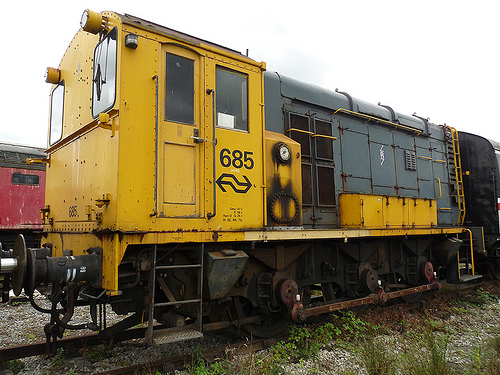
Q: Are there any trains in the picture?
A: Yes, there is a train.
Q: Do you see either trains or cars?
A: Yes, there is a train.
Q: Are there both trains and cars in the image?
A: No, there is a train but no cars.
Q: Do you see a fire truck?
A: No, there are no fire trucks.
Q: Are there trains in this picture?
A: Yes, there is a train.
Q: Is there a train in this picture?
A: Yes, there is a train.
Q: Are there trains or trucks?
A: Yes, there is a train.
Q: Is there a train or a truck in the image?
A: Yes, there is a train.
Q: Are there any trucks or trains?
A: Yes, there is a train.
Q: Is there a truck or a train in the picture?
A: Yes, there is a train.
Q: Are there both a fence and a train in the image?
A: No, there is a train but no fences.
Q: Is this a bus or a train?
A: This is a train.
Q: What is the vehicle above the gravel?
A: The vehicle is a train.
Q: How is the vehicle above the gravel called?
A: The vehicle is a train.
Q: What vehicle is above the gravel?
A: The vehicle is a train.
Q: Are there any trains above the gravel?
A: Yes, there is a train above the gravel.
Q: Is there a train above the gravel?
A: Yes, there is a train above the gravel.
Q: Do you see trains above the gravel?
A: Yes, there is a train above the gravel.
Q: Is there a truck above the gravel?
A: No, there is a train above the gravel.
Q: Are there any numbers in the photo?
A: Yes, there are numbers.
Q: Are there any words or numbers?
A: Yes, there are numbers.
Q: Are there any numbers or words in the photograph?
A: Yes, there are numbers.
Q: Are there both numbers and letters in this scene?
A: No, there are numbers but no letters.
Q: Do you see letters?
A: No, there are no letters.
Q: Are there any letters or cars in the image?
A: No, there are no letters or cars.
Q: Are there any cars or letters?
A: No, there are no letters or cars.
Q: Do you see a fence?
A: No, there are no fences.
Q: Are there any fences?
A: No, there are no fences.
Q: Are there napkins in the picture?
A: No, there are no napkins.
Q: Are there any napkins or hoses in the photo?
A: No, there are no napkins or hoses.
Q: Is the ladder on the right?
A: Yes, the ladder is on the right of the image.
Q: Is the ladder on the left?
A: No, the ladder is on the right of the image.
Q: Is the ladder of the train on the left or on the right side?
A: The ladder is on the right of the image.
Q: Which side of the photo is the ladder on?
A: The ladder is on the right of the image.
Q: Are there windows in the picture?
A: Yes, there is a window.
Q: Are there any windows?
A: Yes, there is a window.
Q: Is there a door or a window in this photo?
A: Yes, there is a window.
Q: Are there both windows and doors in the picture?
A: Yes, there are both a window and a door.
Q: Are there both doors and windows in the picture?
A: Yes, there are both a window and a door.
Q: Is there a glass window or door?
A: Yes, there is a glass window.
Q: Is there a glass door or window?
A: Yes, there is a glass window.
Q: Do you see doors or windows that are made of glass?
A: Yes, the window is made of glass.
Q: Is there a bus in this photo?
A: No, there are no buses.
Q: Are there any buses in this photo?
A: No, there are no buses.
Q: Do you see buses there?
A: No, there are no buses.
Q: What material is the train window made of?
A: The window is made of glass.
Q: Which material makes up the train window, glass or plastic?
A: The window is made of glass.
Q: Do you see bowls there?
A: No, there are no bowls.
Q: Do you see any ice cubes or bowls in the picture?
A: No, there are no bowls or ice cubes.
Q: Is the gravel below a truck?
A: No, the gravel is below the train.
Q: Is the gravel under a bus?
A: No, the gravel is under the train.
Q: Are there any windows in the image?
A: Yes, there is a window.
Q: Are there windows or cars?
A: Yes, there is a window.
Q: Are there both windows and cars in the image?
A: No, there is a window but no cars.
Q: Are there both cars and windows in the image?
A: No, there is a window but no cars.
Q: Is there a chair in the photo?
A: No, there are no chairs.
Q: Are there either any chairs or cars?
A: No, there are no chairs or cars.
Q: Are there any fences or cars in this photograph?
A: No, there are no cars or fences.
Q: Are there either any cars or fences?
A: No, there are no cars or fences.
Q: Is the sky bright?
A: Yes, the sky is bright.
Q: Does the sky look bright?
A: Yes, the sky is bright.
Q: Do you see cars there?
A: No, there are no cars.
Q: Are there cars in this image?
A: No, there are no cars.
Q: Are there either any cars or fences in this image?
A: No, there are no cars or fences.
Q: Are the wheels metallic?
A: Yes, the wheels are metallic.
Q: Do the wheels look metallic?
A: Yes, the wheels are metallic.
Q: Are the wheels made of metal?
A: Yes, the wheels are made of metal.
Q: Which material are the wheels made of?
A: The wheels are made of metal.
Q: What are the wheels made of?
A: The wheels are made of metal.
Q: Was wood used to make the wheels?
A: No, the wheels are made of metal.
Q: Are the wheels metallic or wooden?
A: The wheels are metallic.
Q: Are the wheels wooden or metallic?
A: The wheels are metallic.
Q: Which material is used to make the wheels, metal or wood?
A: The wheels are made of metal.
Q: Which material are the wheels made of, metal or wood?
A: The wheels are made of metal.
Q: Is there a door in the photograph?
A: Yes, there is a door.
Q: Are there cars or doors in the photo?
A: Yes, there is a door.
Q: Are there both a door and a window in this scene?
A: Yes, there are both a door and a window.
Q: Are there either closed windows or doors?
A: Yes, there is a closed door.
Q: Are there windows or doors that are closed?
A: Yes, the door is closed.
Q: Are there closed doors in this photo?
A: Yes, there is a closed door.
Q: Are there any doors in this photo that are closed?
A: Yes, there is a door that is closed.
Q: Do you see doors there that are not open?
A: Yes, there is an closed door.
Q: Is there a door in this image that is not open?
A: Yes, there is an closed door.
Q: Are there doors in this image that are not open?
A: Yes, there is an closed door.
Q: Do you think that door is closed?
A: Yes, the door is closed.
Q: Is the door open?
A: No, the door is closed.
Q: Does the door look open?
A: No, the door is closed.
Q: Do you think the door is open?
A: No, the door is closed.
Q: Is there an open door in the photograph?
A: No, there is a door but it is closed.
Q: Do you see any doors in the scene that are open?
A: No, there is a door but it is closed.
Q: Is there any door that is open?
A: No, there is a door but it is closed.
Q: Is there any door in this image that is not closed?
A: No, there is a door but it is closed.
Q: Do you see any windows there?
A: Yes, there is a window.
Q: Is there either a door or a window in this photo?
A: Yes, there is a window.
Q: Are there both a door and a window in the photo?
A: Yes, there are both a window and a door.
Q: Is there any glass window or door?
A: Yes, there is a glass window.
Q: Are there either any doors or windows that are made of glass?
A: Yes, the window is made of glass.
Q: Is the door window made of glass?
A: Yes, the window is made of glass.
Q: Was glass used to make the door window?
A: Yes, the window is made of glass.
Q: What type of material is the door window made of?
A: The window is made of glass.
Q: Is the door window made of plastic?
A: No, the window is made of glass.